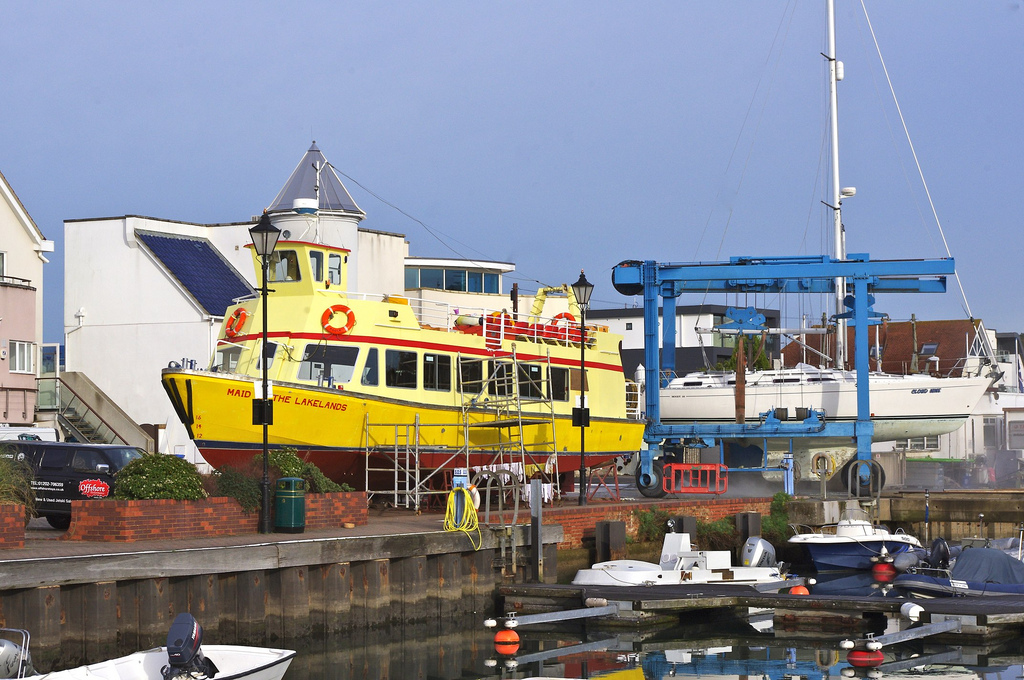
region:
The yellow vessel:
[182, 231, 660, 487]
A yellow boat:
[178, 234, 634, 479]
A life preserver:
[217, 305, 256, 338]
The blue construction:
[597, 238, 968, 492]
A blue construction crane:
[603, 241, 957, 489]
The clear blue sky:
[5, 92, 1021, 321]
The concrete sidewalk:
[4, 515, 520, 566]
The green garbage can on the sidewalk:
[267, 463, 321, 518]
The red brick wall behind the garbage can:
[59, 493, 392, 529]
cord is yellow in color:
[420, 477, 518, 566]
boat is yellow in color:
[159, 207, 679, 508]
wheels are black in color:
[641, 453, 665, 492]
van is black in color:
[8, 427, 148, 544]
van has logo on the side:
[69, 471, 127, 509]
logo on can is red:
[74, 472, 114, 504]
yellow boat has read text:
[227, 379, 365, 424]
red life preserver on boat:
[314, 294, 379, 355]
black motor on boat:
[147, 604, 231, 669]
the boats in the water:
[3, 512, 1022, 677]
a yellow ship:
[163, 221, 650, 466]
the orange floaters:
[493, 553, 893, 656]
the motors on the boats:
[161, 522, 775, 666]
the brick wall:
[0, 481, 375, 552]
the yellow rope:
[435, 481, 484, 538]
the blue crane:
[607, 240, 962, 497]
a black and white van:
[2, 436, 148, 523]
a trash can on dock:
[272, 462, 314, 538]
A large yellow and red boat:
[151, 214, 689, 566]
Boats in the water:
[562, 502, 940, 673]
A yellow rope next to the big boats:
[401, 436, 501, 596]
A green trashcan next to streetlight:
[245, 441, 348, 540]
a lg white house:
[47, 161, 362, 506]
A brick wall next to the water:
[126, 518, 455, 671]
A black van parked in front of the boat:
[0, 416, 177, 554]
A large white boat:
[623, 258, 987, 465]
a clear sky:
[613, 88, 814, 136]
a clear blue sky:
[454, 38, 579, 131]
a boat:
[167, 262, 594, 479]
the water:
[410, 622, 455, 664]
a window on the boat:
[297, 333, 358, 387]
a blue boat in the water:
[878, 528, 1016, 612]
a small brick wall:
[119, 500, 173, 540]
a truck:
[43, 437, 116, 494]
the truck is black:
[31, 449, 88, 511]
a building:
[10, 202, 37, 427]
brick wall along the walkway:
[6, 493, 362, 538]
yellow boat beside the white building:
[168, 235, 631, 473]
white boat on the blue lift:
[628, 329, 993, 441]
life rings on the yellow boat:
[217, 300, 361, 338]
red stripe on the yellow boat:
[241, 316, 622, 378]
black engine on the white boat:
[157, 608, 225, 678]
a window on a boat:
[205, 346, 240, 369]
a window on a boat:
[298, 333, 359, 381]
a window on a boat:
[360, 343, 380, 386]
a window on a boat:
[379, 342, 419, 397]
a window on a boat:
[422, 339, 455, 379]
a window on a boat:
[453, 345, 483, 391]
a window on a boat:
[484, 356, 511, 396]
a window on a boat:
[511, 359, 550, 397]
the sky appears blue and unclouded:
[3, 2, 1022, 350]